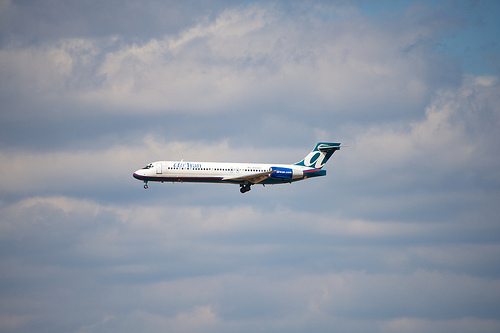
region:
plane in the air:
[124, 108, 398, 249]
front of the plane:
[125, 145, 168, 193]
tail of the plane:
[287, 123, 361, 195]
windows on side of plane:
[160, 138, 295, 190]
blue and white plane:
[116, 117, 347, 224]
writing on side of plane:
[167, 154, 210, 179]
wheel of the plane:
[133, 178, 167, 201]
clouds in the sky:
[51, 58, 158, 168]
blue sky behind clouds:
[385, 39, 491, 117]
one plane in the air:
[97, 113, 374, 230]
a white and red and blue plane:
[123, 141, 340, 188]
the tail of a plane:
[298, 136, 337, 165]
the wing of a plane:
[223, 170, 273, 185]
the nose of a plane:
[132, 160, 154, 176]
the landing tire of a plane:
[142, 182, 149, 191]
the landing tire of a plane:
[238, 184, 243, 192]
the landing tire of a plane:
[242, 182, 250, 192]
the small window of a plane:
[165, 164, 168, 172]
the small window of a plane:
[147, 163, 152, 167]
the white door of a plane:
[156, 161, 162, 175]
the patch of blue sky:
[440, 23, 496, 73]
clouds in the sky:
[49, 20, 355, 122]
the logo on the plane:
[309, 148, 326, 169]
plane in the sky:
[93, 133, 355, 213]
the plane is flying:
[123, 137, 341, 206]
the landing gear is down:
[135, 178, 156, 191]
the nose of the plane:
[127, 170, 143, 181]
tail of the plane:
[293, 130, 334, 167]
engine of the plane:
[267, 165, 309, 187]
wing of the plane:
[216, 164, 276, 191]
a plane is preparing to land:
[122, 131, 352, 213]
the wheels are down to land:
[130, 140, 341, 195]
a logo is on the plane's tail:
[292, 139, 339, 177]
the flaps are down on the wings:
[222, 165, 279, 192]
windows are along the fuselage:
[165, 165, 287, 175]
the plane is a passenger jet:
[130, 138, 342, 200]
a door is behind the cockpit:
[153, 160, 163, 178]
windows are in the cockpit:
[132, 157, 158, 182]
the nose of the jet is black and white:
[129, 165, 143, 182]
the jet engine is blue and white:
[253, 162, 317, 187]